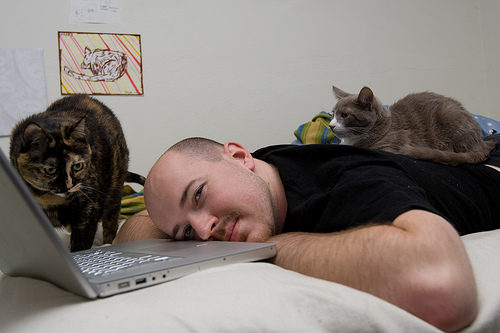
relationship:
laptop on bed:
[0, 144, 277, 299] [0, 219, 499, 333]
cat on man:
[329, 85, 497, 165] [110, 138, 500, 332]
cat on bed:
[10, 95, 130, 253] [0, 219, 499, 333]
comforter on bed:
[0, 217, 499, 331] [0, 219, 499, 333]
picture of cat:
[57, 31, 145, 97] [63, 45, 127, 81]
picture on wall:
[57, 31, 145, 97] [0, 1, 499, 193]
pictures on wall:
[57, 31, 145, 97] [0, 1, 499, 193]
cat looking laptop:
[10, 95, 130, 253] [0, 144, 277, 299]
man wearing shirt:
[110, 138, 500, 332] [250, 144, 500, 237]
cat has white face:
[329, 85, 497, 165] [328, 104, 352, 145]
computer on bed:
[0, 144, 277, 299] [0, 219, 499, 333]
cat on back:
[329, 85, 497, 165] [250, 143, 499, 236]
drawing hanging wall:
[57, 31, 145, 97] [0, 1, 499, 193]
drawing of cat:
[57, 31, 145, 97] [63, 45, 127, 81]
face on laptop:
[143, 162, 274, 242] [0, 144, 277, 299]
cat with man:
[329, 85, 497, 165] [110, 138, 500, 332]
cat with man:
[10, 95, 130, 253] [110, 138, 500, 332]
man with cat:
[110, 138, 500, 332] [329, 85, 497, 165]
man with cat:
[110, 138, 500, 332] [10, 95, 130, 253]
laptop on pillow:
[0, 144, 277, 299] [0, 219, 499, 333]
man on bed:
[110, 138, 500, 332] [0, 219, 499, 333]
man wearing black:
[110, 138, 500, 332] [250, 144, 500, 237]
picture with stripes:
[57, 31, 145, 97] [59, 33, 143, 98]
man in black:
[110, 138, 500, 332] [250, 144, 500, 237]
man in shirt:
[110, 138, 500, 332] [250, 144, 500, 237]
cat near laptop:
[10, 95, 130, 253] [0, 144, 277, 299]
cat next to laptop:
[10, 95, 130, 253] [0, 144, 277, 299]